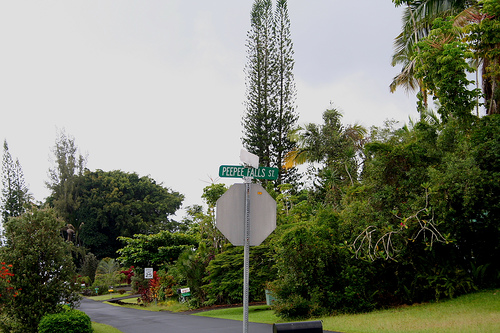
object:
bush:
[36, 307, 91, 331]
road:
[74, 293, 273, 333]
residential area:
[0, 0, 497, 333]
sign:
[210, 181, 276, 248]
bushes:
[264, 118, 500, 324]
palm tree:
[387, 0, 496, 116]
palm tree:
[389, 17, 433, 123]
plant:
[124, 263, 158, 303]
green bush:
[36, 306, 93, 331]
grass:
[193, 254, 499, 333]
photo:
[0, 0, 500, 331]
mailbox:
[180, 287, 190, 293]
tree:
[243, 0, 300, 191]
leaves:
[410, 0, 500, 104]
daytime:
[0, 0, 497, 225]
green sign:
[219, 165, 279, 180]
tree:
[264, 218, 337, 319]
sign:
[144, 267, 154, 279]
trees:
[0, 203, 87, 333]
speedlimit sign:
[141, 266, 154, 280]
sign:
[217, 165, 280, 180]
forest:
[113, 0, 496, 327]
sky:
[4, 1, 431, 203]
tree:
[193, 246, 274, 309]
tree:
[118, 229, 203, 303]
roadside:
[74, 296, 275, 331]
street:
[70, 297, 273, 333]